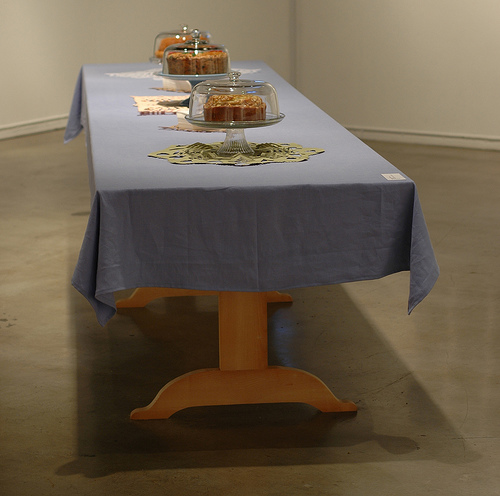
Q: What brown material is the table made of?
A: Wood.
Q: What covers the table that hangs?
A: Table cloth.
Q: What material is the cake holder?
A: Glass.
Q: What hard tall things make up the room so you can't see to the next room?
A: Walls.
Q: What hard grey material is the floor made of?
A: Cement.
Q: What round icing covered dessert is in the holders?
A: Cakes.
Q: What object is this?
A: Table.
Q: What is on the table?
A: Food containers.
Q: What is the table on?
A: Floor.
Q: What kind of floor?
A: Concrete.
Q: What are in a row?
A: Cakes.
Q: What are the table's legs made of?
A: Wood.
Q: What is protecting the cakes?
A: Cases.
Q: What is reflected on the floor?
A: Shadows.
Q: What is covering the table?
A: Tablecloth.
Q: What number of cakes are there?
A: 3.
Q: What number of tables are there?
A: 1.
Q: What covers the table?
A: Tablecloth.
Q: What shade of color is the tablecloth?
A: Blue.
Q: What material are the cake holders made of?
A: Glass.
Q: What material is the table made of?
A: Wood.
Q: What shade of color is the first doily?
A: Green.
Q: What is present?
A: A table.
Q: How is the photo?
A: Clear.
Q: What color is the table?
A: Brown.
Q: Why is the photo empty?
A: There is noone.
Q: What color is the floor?
A: Grey.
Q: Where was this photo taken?
A: At a contest.